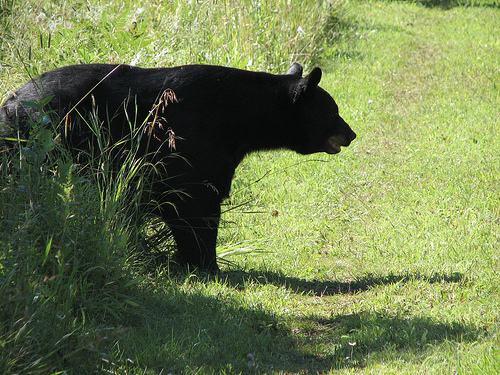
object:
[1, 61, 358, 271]
bear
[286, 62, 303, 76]
ear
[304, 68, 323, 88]
ear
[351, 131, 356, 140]
nose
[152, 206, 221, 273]
legs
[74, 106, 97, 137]
grass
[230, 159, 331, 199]
grass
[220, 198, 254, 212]
grass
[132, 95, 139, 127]
grass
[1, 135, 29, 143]
grass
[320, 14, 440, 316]
track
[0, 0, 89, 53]
grass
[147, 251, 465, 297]
shadow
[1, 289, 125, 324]
grass clump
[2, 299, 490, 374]
shadow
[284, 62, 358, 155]
head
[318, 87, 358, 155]
face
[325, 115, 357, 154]
snout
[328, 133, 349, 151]
mouth